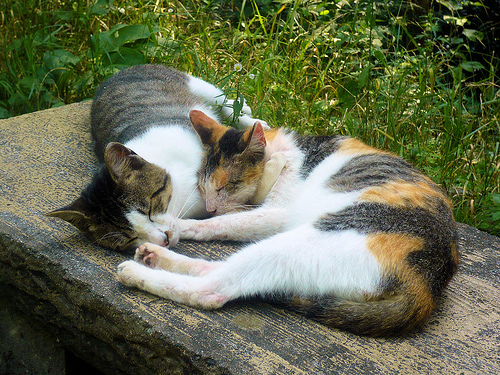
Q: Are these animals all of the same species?
A: Yes, all the animals are cats.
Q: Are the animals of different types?
A: No, all the animals are cats.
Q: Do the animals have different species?
A: No, all the animals are cats.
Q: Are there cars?
A: No, there are no cars.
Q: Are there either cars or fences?
A: No, there are no cars or fences.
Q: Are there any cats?
A: Yes, there is a cat.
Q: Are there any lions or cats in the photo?
A: Yes, there is a cat.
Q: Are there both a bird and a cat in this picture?
A: No, there is a cat but no birds.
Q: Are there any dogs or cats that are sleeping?
A: Yes, the cat is sleeping.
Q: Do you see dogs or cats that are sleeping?
A: Yes, the cat is sleeping.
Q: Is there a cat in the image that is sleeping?
A: Yes, there is a cat that is sleeping.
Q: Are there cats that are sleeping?
A: Yes, there is a cat that is sleeping.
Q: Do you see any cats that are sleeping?
A: Yes, there is a cat that is sleeping.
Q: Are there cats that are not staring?
A: Yes, there is a cat that is sleeping.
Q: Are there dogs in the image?
A: No, there are no dogs.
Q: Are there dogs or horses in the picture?
A: No, there are no dogs or horses.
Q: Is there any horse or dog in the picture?
A: No, there are no dogs or horses.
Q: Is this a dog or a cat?
A: This is a cat.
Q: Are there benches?
A: Yes, there is a bench.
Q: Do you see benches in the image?
A: Yes, there is a bench.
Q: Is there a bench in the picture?
A: Yes, there is a bench.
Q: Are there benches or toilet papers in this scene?
A: Yes, there is a bench.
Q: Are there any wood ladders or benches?
A: Yes, there is a wood bench.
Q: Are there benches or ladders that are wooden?
A: Yes, the bench is wooden.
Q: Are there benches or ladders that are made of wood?
A: Yes, the bench is made of wood.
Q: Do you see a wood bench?
A: Yes, there is a bench that is made of wood.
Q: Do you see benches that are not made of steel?
A: Yes, there is a bench that is made of wood.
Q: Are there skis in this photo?
A: No, there are no skis.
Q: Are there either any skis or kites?
A: No, there are no skis or kites.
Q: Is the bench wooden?
A: Yes, the bench is wooden.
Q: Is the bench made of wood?
A: Yes, the bench is made of wood.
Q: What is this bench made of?
A: The bench is made of wood.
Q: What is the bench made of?
A: The bench is made of wood.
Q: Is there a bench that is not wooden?
A: No, there is a bench but it is wooden.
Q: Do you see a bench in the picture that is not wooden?
A: No, there is a bench but it is wooden.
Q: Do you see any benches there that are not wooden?
A: No, there is a bench but it is wooden.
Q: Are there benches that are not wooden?
A: No, there is a bench but it is wooden.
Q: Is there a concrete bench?
A: No, there is a bench but it is made of wood.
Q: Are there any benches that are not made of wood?
A: No, there is a bench but it is made of wood.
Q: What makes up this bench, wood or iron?
A: The bench is made of wood.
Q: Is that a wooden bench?
A: Yes, that is a wooden bench.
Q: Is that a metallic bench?
A: No, that is a wooden bench.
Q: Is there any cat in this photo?
A: Yes, there are cats.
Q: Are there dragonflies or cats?
A: Yes, there are cats.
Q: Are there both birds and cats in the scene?
A: No, there are cats but no birds.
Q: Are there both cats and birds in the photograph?
A: No, there are cats but no birds.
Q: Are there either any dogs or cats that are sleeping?
A: Yes, the cats are sleeping.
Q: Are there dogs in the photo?
A: No, there are no dogs.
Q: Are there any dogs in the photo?
A: No, there are no dogs.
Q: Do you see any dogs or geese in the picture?
A: No, there are no dogs or geese.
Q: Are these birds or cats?
A: These are cats.